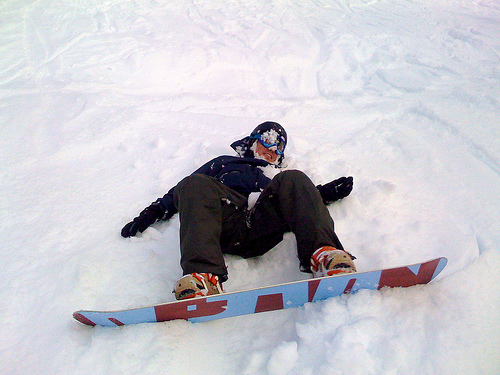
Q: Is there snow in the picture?
A: Yes, there is snow.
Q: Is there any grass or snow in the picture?
A: Yes, there is snow.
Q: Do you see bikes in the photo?
A: No, there are no bikes.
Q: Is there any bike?
A: No, there are no bikes.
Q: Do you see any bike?
A: No, there are no bikes.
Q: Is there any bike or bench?
A: No, there are no bikes or benches.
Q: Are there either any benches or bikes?
A: No, there are no bikes or benches.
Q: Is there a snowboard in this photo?
A: Yes, there is a snowboard.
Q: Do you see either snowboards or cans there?
A: Yes, there is a snowboard.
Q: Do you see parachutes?
A: No, there are no parachutes.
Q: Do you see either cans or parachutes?
A: No, there are no parachutes or cans.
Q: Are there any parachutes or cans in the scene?
A: No, there are no parachutes or cans.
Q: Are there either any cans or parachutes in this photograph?
A: No, there are no parachutes or cans.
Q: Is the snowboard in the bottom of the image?
A: Yes, the snowboard is in the bottom of the image.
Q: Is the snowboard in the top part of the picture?
A: No, the snowboard is in the bottom of the image.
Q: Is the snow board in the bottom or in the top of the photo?
A: The snow board is in the bottom of the image.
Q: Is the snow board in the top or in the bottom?
A: The snow board is in the bottom of the image.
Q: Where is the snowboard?
A: The snowboard is on the snow.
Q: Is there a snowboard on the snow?
A: Yes, there is a snowboard on the snow.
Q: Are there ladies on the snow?
A: No, there is a snowboard on the snow.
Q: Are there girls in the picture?
A: No, there are no girls.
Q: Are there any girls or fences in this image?
A: No, there are no girls or fences.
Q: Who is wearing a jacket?
A: The man is wearing a jacket.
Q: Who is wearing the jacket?
A: The man is wearing a jacket.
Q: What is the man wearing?
A: The man is wearing a jacket.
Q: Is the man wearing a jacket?
A: Yes, the man is wearing a jacket.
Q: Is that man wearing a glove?
A: No, the man is wearing a jacket.